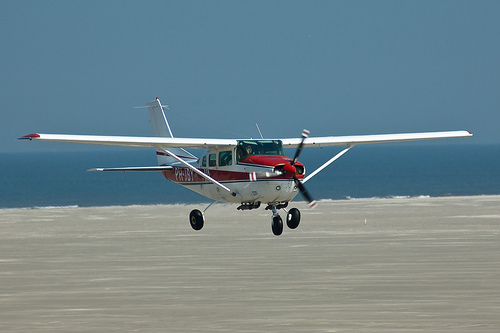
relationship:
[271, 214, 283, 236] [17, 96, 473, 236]
tire on plane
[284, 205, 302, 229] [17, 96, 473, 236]
tire on plane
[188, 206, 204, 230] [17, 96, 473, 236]
tire on plane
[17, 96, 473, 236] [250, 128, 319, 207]
plane has a propeller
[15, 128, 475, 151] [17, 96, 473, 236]
wing on plane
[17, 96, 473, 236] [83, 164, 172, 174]
plane has a wing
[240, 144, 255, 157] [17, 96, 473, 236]
pilot in plane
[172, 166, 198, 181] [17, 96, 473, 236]
writing on plane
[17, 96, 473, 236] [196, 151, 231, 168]
plane has windows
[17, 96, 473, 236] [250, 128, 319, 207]
plane has propeller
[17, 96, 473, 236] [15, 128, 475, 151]
plane has wing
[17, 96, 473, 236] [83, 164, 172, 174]
plane has wing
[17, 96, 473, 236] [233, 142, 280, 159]
plane has windshield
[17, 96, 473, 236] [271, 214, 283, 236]
plane has tire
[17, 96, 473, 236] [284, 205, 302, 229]
plane has tire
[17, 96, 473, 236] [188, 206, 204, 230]
plane has tire